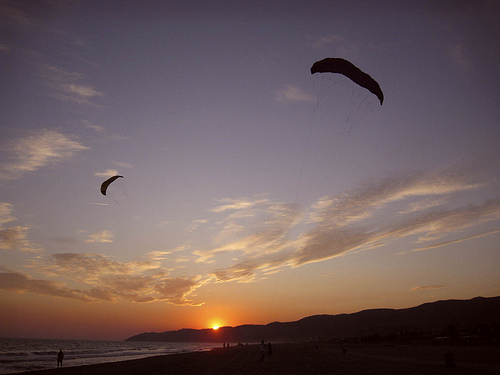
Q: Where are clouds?
A: In the sky.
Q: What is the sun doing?
A: Setting.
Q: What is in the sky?
A: Skydivers.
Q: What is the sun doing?
A: Setting.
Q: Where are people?
A: On the beach.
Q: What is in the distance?
A: Mountains.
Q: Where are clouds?
A: In the sky.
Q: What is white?
A: Clouds.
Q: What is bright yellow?
A: Sun.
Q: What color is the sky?
A: Blue.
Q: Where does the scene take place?
A: At the beach.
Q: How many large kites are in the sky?
A: Two.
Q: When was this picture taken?
A: Sunset.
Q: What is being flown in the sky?
A: Kites.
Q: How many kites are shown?
A: Two.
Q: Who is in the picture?
A: Men and women.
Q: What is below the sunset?
A: Water.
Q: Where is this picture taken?
A: A beach.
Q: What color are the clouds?
A: White.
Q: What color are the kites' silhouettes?
A: Black.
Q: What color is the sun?
A: Gold and orange.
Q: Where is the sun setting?
A: On a mountain.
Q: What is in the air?
A: A black parachute.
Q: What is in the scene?
A: A dark mountain.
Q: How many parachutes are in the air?
A: Two parachutes.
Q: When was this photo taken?
A: Late evening.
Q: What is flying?
A: Kites.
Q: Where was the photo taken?
A: At the beach.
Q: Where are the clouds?
A: In the sky.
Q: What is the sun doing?
A: Setting.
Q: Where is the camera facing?
A: The west.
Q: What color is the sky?
A: Blue.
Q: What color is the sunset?
A: Orange.